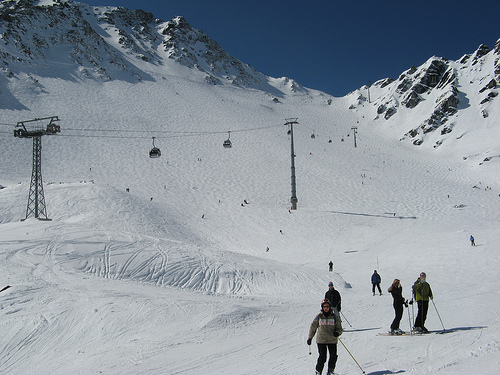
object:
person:
[303, 293, 347, 375]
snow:
[0, 1, 499, 374]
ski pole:
[334, 336, 366, 374]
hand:
[332, 330, 340, 337]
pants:
[312, 343, 340, 373]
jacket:
[306, 310, 344, 345]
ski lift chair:
[148, 146, 163, 159]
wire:
[55, 124, 288, 138]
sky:
[87, 0, 498, 96]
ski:
[379, 293, 383, 296]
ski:
[372, 292, 376, 297]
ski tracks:
[116, 249, 141, 280]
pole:
[284, 115, 301, 210]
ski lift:
[0, 82, 372, 219]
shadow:
[342, 326, 379, 333]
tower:
[7, 111, 65, 221]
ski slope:
[0, 78, 498, 374]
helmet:
[319, 297, 332, 307]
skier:
[383, 275, 411, 338]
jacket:
[386, 286, 404, 305]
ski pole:
[406, 298, 413, 337]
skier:
[411, 267, 434, 335]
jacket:
[410, 279, 435, 304]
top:
[68, 0, 190, 32]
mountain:
[0, 1, 309, 101]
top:
[472, 34, 499, 56]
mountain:
[345, 24, 500, 160]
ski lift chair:
[222, 138, 235, 149]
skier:
[323, 279, 344, 320]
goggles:
[328, 284, 334, 287]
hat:
[327, 281, 334, 287]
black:
[388, 283, 406, 329]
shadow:
[235, 71, 284, 99]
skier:
[368, 269, 383, 298]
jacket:
[371, 273, 381, 284]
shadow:
[429, 324, 488, 333]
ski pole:
[430, 296, 446, 330]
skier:
[468, 234, 479, 251]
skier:
[265, 246, 270, 252]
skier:
[243, 198, 249, 205]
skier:
[201, 213, 206, 218]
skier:
[217, 198, 223, 205]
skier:
[149, 196, 155, 203]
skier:
[361, 180, 365, 186]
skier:
[163, 183, 168, 190]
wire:
[297, 123, 351, 136]